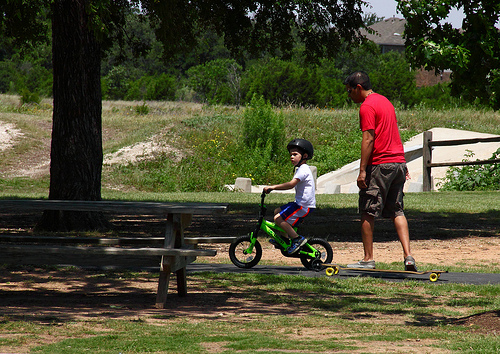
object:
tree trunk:
[46, 0, 104, 211]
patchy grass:
[49, 318, 207, 354]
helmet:
[285, 139, 315, 161]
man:
[344, 70, 416, 273]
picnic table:
[0, 195, 228, 307]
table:
[0, 192, 234, 310]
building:
[361, 10, 420, 64]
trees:
[240, 81, 288, 156]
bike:
[229, 186, 333, 271]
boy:
[261, 136, 318, 252]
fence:
[424, 127, 500, 191]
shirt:
[358, 93, 403, 165]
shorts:
[358, 162, 407, 220]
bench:
[2, 197, 234, 310]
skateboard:
[322, 261, 449, 286]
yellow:
[325, 268, 335, 275]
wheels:
[427, 271, 440, 283]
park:
[2, 91, 499, 352]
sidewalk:
[99, 258, 499, 286]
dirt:
[442, 236, 472, 260]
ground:
[0, 273, 500, 354]